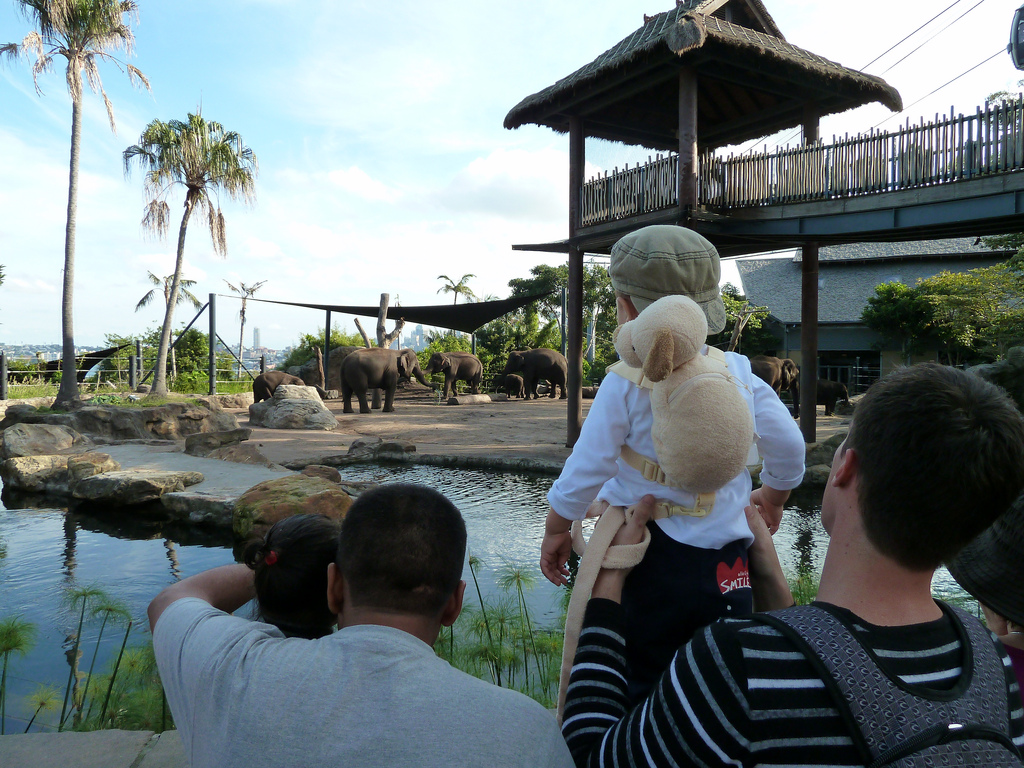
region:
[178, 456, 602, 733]
tourist at a zoo pen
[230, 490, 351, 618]
tourist at a zoo pen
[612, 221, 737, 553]
tourist at a zoo pen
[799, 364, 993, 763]
tourist at a zoo pen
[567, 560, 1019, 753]
striped shirt on boy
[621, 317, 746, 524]
teddy bear backpack on kid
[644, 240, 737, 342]
backwards green hat on boy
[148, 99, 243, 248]
palm tree above pen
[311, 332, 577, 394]
elephants standing in pen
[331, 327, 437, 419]
the elephant is gray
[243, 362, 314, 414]
the elephant is gray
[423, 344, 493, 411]
the elephant is gray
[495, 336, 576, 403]
the elephant is gray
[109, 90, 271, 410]
a palm is green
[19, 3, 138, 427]
a palm is green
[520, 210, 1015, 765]
person holding a baby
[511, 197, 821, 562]
baby has a plush on his back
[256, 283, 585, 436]
trees behind the elephants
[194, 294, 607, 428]
a small herd of elephants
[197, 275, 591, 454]
these elephants are in captivity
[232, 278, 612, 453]
these are elephants in a zoo exhibit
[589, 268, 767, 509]
this is a puppy backpack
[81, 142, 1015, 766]
the people are looking at the elephants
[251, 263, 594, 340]
this is a canopy tarp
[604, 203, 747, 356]
this is a green cap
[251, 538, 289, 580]
this is a red hair rubber band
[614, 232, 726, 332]
person has a head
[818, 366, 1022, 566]
person has a head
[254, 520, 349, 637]
person has a head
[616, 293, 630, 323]
person has an ear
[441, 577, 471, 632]
person has an ear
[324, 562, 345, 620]
person has an ear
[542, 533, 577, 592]
person has a hand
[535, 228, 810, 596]
small child wearing back pack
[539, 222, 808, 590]
small child wearing olive green hat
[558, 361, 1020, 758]
young boy holding the small child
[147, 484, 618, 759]
man standing behind young girl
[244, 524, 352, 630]
young girl observing the elephants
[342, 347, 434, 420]
adult elephant standing in habitat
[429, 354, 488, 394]
adult elephant standing in habitat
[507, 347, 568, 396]
adult elephant standing in habitat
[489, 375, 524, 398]
baby elephant standing in habitat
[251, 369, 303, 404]
adult elephant standing in habitat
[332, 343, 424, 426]
A large grey elephant.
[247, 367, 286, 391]
A large grey elephant.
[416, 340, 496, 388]
A large grey elephant.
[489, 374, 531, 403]
A large grey elephant.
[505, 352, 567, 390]
A large grey elephant.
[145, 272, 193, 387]
A tree in a city.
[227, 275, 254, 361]
A tree in a city.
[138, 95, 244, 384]
A tree in a city.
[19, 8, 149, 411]
A tree in a city.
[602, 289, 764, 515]
tan dog backpack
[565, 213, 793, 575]
boy held by man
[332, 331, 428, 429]
gray colored elephant in enclosure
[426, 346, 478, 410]
gray colored elephant in enclosure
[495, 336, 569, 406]
gray colored elephant in enclosure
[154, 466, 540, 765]
man and woman by enclosure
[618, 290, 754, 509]
backpack on a young child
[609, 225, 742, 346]
green hat on a young child